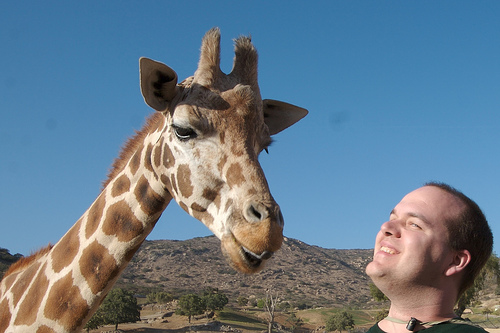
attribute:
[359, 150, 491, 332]
man — smiling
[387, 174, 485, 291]
head — here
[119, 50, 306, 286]
head — here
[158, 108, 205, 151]
eye — here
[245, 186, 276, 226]
nostril — here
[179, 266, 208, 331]
tree — pictured, here, present, small, green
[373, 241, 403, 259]
mouth — here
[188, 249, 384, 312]
hill — here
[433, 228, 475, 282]
ear — here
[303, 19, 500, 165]
sky — blue, here